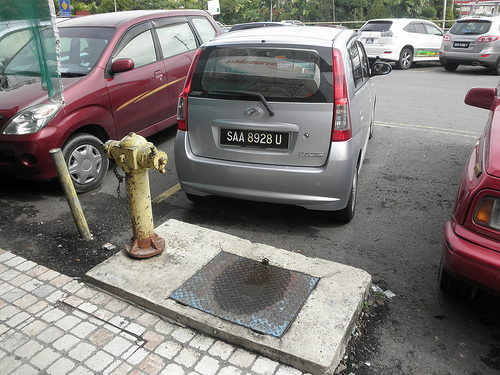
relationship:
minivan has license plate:
[170, 23, 378, 223] [219, 126, 289, 148]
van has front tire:
[0, 10, 219, 191] [64, 137, 110, 193]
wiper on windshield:
[210, 89, 272, 118] [193, 46, 333, 105]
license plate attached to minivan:
[219, 126, 289, 148] [170, 23, 378, 223]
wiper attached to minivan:
[210, 89, 272, 118] [170, 23, 378, 223]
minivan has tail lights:
[170, 23, 378, 223] [331, 47, 353, 141]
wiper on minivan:
[210, 89, 272, 118] [170, 23, 378, 223]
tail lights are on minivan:
[331, 47, 353, 141] [170, 23, 378, 223]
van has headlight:
[0, 10, 219, 191] [3, 100, 67, 137]